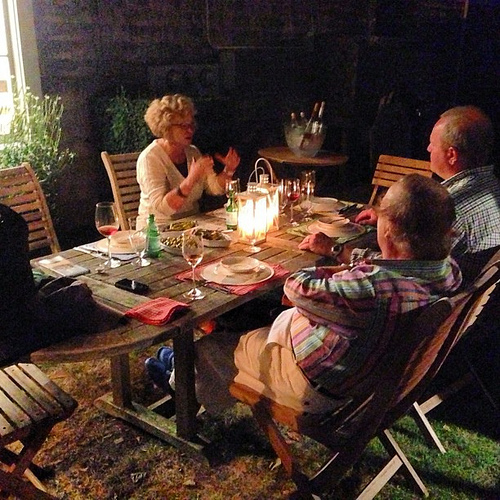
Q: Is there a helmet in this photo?
A: No, there are no helmets.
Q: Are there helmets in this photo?
A: No, there are no helmets.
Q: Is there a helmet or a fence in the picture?
A: No, there are no helmets or fences.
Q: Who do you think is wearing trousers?
A: The man is wearing trousers.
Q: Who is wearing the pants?
A: The man is wearing trousers.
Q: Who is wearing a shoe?
A: The man is wearing a shoe.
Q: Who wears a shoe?
A: The man wears a shoe.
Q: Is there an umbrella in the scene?
A: No, there are no umbrellas.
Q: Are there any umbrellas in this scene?
A: No, there are no umbrellas.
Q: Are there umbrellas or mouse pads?
A: No, there are no umbrellas or mouse pads.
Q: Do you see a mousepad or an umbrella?
A: No, there are no umbrellas or mouse pads.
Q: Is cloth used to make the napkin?
A: Yes, the napkin is made of cloth.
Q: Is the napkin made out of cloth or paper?
A: The napkin is made of cloth.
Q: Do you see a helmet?
A: No, there are no helmets.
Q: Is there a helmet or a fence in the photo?
A: No, there are no helmets or fences.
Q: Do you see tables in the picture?
A: Yes, there is a table.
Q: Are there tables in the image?
A: Yes, there is a table.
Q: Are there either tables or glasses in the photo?
A: Yes, there is a table.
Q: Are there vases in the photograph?
A: No, there are no vases.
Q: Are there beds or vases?
A: No, there are no vases or beds.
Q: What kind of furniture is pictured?
A: The furniture is a table.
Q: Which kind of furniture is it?
A: The piece of furniture is a table.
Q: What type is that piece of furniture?
A: That is a table.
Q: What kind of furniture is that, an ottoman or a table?
A: That is a table.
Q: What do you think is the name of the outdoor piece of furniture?
A: The piece of furniture is a table.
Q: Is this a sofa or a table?
A: This is a table.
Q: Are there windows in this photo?
A: Yes, there is a window.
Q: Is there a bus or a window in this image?
A: Yes, there is a window.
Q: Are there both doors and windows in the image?
A: No, there is a window but no doors.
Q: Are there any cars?
A: No, there are no cars.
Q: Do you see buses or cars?
A: No, there are no cars or buses.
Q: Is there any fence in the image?
A: No, there are no fences.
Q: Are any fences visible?
A: No, there are no fences.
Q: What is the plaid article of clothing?
A: The clothing item is a shirt.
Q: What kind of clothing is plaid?
A: The clothing is a shirt.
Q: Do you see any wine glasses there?
A: Yes, there is a wine glass.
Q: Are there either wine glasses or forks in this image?
A: Yes, there is a wine glass.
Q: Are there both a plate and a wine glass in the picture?
A: Yes, there are both a wine glass and a plate.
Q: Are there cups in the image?
A: No, there are no cups.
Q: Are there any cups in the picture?
A: No, there are no cups.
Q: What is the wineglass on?
A: The wineglass is on the table.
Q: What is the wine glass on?
A: The wineglass is on the table.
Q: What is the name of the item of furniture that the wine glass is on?
A: The piece of furniture is a table.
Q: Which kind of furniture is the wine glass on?
A: The wine glass is on the table.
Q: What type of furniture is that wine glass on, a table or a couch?
A: The wine glass is on a table.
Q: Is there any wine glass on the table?
A: Yes, there is a wine glass on the table.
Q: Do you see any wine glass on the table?
A: Yes, there is a wine glass on the table.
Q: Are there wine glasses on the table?
A: Yes, there is a wine glass on the table.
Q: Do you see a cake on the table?
A: No, there is a wine glass on the table.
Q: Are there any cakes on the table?
A: No, there is a wine glass on the table.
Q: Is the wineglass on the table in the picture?
A: Yes, the wineglass is on the table.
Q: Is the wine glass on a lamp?
A: No, the wine glass is on the table.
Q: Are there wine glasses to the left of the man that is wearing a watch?
A: Yes, there is a wine glass to the left of the man.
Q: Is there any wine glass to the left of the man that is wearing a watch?
A: Yes, there is a wine glass to the left of the man.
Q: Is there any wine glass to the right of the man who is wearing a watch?
A: No, the wine glass is to the left of the man.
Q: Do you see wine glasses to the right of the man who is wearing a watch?
A: No, the wine glass is to the left of the man.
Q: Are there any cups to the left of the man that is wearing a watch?
A: No, there is a wine glass to the left of the man.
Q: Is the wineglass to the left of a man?
A: Yes, the wineglass is to the left of a man.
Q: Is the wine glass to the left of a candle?
A: No, the wine glass is to the left of a man.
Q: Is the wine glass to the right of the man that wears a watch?
A: No, the wine glass is to the left of the man.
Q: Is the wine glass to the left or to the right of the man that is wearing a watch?
A: The wine glass is to the left of the man.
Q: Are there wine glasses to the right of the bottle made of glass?
A: Yes, there is a wine glass to the right of the bottle.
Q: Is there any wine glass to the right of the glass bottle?
A: Yes, there is a wine glass to the right of the bottle.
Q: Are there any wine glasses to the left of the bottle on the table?
A: No, the wine glass is to the right of the bottle.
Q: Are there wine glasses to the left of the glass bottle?
A: No, the wine glass is to the right of the bottle.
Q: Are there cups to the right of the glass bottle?
A: No, there is a wine glass to the right of the bottle.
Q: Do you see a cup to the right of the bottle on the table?
A: No, there is a wine glass to the right of the bottle.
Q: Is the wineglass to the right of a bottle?
A: Yes, the wineglass is to the right of a bottle.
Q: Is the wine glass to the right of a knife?
A: No, the wine glass is to the right of a bottle.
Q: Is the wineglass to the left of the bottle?
A: No, the wineglass is to the right of the bottle.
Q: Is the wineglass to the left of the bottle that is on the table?
A: No, the wineglass is to the right of the bottle.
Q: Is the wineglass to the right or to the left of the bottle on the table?
A: The wineglass is to the right of the bottle.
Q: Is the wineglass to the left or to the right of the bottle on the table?
A: The wineglass is to the right of the bottle.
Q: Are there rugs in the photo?
A: No, there are no rugs.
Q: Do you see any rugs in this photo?
A: No, there are no rugs.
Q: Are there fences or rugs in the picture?
A: No, there are no rugs or fences.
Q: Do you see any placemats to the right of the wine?
A: Yes, there is a placemat to the right of the wine.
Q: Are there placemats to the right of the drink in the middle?
A: Yes, there is a placemat to the right of the wine.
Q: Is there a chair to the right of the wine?
A: No, there is a placemat to the right of the wine.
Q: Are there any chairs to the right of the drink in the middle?
A: No, there is a placemat to the right of the wine.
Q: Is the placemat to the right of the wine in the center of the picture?
A: Yes, the placemat is to the right of the wine.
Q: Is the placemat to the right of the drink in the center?
A: Yes, the placemat is to the right of the wine.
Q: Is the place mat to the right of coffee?
A: No, the place mat is to the right of the wine.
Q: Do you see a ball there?
A: No, there are no balls.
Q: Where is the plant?
A: The plant is at the window.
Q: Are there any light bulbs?
A: No, there are no light bulbs.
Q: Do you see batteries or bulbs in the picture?
A: No, there are no bulbs or batteries.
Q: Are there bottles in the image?
A: Yes, there is a bottle.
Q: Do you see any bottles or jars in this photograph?
A: Yes, there is a bottle.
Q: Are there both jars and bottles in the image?
A: No, there is a bottle but no jars.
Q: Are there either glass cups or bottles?
A: Yes, there is a glass bottle.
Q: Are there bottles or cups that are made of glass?
A: Yes, the bottle is made of glass.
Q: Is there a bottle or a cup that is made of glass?
A: Yes, the bottle is made of glass.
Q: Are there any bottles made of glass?
A: Yes, there is a bottle that is made of glass.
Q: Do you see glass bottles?
A: Yes, there is a bottle that is made of glass.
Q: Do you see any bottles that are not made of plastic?
A: Yes, there is a bottle that is made of glass.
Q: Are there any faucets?
A: No, there are no faucets.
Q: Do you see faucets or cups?
A: No, there are no faucets or cups.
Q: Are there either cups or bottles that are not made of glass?
A: No, there is a bottle but it is made of glass.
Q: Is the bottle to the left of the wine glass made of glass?
A: Yes, the bottle is made of glass.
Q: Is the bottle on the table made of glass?
A: Yes, the bottle is made of glass.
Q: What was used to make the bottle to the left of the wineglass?
A: The bottle is made of glass.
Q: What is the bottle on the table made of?
A: The bottle is made of glass.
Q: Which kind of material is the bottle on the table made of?
A: The bottle is made of glass.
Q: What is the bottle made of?
A: The bottle is made of glass.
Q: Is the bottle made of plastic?
A: No, the bottle is made of glass.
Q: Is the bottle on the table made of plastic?
A: No, the bottle is made of glass.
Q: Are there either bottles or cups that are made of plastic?
A: No, there is a bottle but it is made of glass.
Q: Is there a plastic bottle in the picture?
A: No, there is a bottle but it is made of glass.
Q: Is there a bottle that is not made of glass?
A: No, there is a bottle but it is made of glass.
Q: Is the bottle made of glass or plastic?
A: The bottle is made of glass.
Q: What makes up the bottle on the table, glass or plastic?
A: The bottle is made of glass.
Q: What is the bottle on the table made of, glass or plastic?
A: The bottle is made of glass.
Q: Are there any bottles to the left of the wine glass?
A: Yes, there is a bottle to the left of the wine glass.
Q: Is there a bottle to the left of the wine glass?
A: Yes, there is a bottle to the left of the wine glass.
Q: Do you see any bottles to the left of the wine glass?
A: Yes, there is a bottle to the left of the wine glass.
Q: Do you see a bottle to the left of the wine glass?
A: Yes, there is a bottle to the left of the wine glass.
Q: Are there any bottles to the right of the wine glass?
A: No, the bottle is to the left of the wine glass.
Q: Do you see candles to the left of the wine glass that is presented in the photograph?
A: No, there is a bottle to the left of the wine glass.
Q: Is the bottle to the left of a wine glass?
A: Yes, the bottle is to the left of a wine glass.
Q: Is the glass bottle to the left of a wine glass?
A: Yes, the bottle is to the left of a wine glass.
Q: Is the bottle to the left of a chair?
A: No, the bottle is to the left of a wine glass.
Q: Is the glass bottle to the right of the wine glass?
A: No, the bottle is to the left of the wine glass.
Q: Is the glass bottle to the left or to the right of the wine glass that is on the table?
A: The bottle is to the left of the wine glass.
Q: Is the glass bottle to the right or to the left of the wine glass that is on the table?
A: The bottle is to the left of the wine glass.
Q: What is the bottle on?
A: The bottle is on the table.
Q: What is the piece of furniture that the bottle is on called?
A: The piece of furniture is a table.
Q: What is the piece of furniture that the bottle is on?
A: The piece of furniture is a table.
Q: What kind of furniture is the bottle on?
A: The bottle is on the table.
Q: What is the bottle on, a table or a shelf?
A: The bottle is on a table.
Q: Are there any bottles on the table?
A: Yes, there is a bottle on the table.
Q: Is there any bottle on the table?
A: Yes, there is a bottle on the table.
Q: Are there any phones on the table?
A: No, there is a bottle on the table.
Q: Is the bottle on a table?
A: Yes, the bottle is on a table.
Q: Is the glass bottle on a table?
A: Yes, the bottle is on a table.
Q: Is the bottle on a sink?
A: No, the bottle is on a table.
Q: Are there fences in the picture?
A: No, there are no fences.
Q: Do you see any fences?
A: No, there are no fences.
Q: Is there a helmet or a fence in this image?
A: No, there are no fences or helmets.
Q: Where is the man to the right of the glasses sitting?
A: The man is sitting at the table.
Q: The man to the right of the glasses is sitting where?
A: The man is sitting at the table.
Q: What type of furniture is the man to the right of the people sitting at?
A: The man is sitting at the table.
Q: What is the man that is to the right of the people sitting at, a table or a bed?
A: The man is sitting at a table.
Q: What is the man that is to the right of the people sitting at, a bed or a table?
A: The man is sitting at a table.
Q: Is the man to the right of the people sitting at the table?
A: Yes, the man is sitting at the table.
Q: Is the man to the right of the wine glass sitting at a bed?
A: No, the man is sitting at the table.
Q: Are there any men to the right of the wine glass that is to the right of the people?
A: Yes, there is a man to the right of the wineglass.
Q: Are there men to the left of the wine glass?
A: No, the man is to the right of the wine glass.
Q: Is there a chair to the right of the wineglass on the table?
A: No, there is a man to the right of the wine glass.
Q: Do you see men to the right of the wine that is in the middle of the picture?
A: Yes, there is a man to the right of the wine.